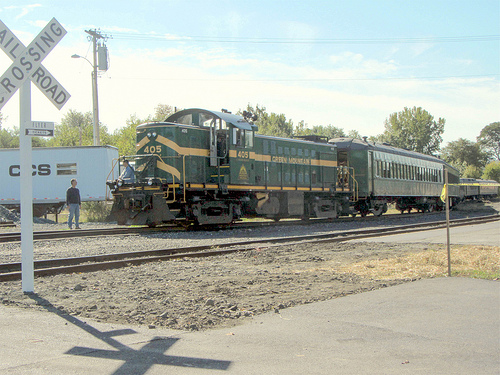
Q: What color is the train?
A: Green.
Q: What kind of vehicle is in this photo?
A: A train.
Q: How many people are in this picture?
A: One.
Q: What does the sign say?
A: Railroad crossing.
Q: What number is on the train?
A: 405.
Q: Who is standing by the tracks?
A: The man.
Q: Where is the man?
A: Next to the train track.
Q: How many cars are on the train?
A: Two.